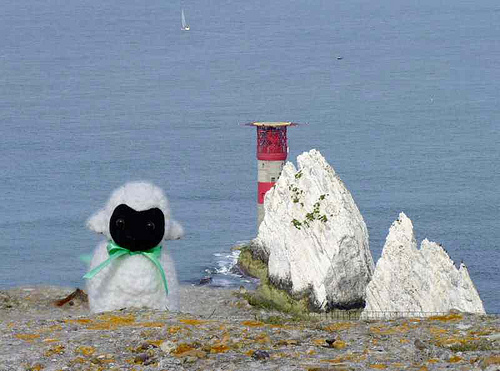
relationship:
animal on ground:
[86, 180, 183, 313] [5, 307, 499, 370]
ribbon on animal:
[85, 241, 169, 296] [86, 180, 183, 313]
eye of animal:
[146, 221, 155, 229] [86, 180, 183, 313]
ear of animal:
[167, 219, 182, 244] [85, 181, 186, 302]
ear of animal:
[167, 219, 181, 240] [85, 181, 186, 302]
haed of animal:
[117, 183, 162, 216] [85, 181, 186, 302]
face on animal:
[112, 207, 163, 251] [86, 180, 183, 313]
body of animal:
[82, 242, 176, 311] [86, 180, 183, 313]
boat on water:
[179, 7, 190, 33] [2, 1, 499, 119]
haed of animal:
[84, 179, 183, 248] [86, 180, 183, 313]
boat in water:
[179, 7, 190, 33] [2, 1, 499, 119]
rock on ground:
[362, 212, 485, 317] [5, 307, 499, 370]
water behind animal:
[2, 1, 499, 119] [85, 181, 186, 302]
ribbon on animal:
[85, 241, 169, 296] [85, 181, 186, 302]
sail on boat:
[181, 6, 187, 26] [179, 7, 190, 33]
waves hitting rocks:
[210, 245, 242, 282] [236, 244, 260, 278]